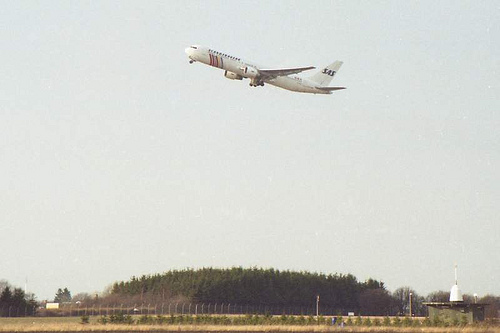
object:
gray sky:
[73, 105, 464, 240]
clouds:
[0, 0, 498, 300]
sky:
[2, 0, 498, 302]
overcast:
[0, 1, 497, 301]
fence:
[59, 267, 442, 327]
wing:
[315, 85, 347, 91]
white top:
[448, 262, 465, 302]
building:
[46, 302, 60, 309]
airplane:
[185, 44, 348, 95]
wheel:
[189, 60, 194, 64]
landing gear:
[248, 79, 264, 88]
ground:
[442, 70, 487, 115]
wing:
[258, 65, 316, 81]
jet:
[166, 23, 374, 132]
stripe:
[209, 53, 223, 69]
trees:
[0, 264, 499, 319]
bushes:
[78, 314, 470, 329]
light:
[316, 294, 320, 316]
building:
[422, 264, 490, 329]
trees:
[77, 309, 474, 331]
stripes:
[210, 52, 223, 67]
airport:
[103, 291, 397, 304]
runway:
[0, 310, 498, 328]